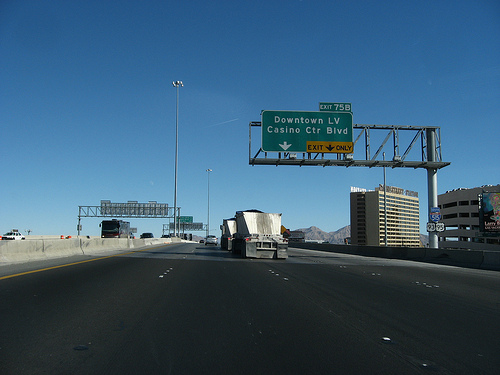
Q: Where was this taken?
A: Freeway.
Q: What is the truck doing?
A: Driving.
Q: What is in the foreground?
A: A sign.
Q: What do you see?
A: A truck.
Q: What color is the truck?
A: White.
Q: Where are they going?
A: East.